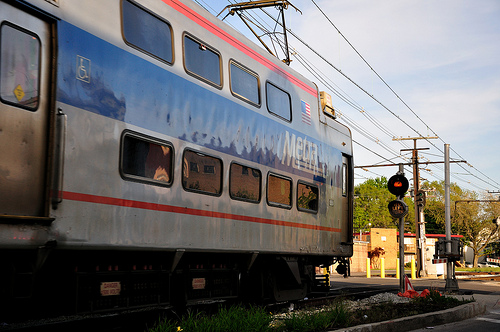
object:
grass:
[187, 302, 348, 331]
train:
[0, 0, 357, 292]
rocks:
[274, 292, 423, 321]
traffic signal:
[387, 167, 420, 295]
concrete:
[393, 253, 499, 318]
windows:
[116, 128, 321, 215]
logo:
[275, 129, 330, 178]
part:
[416, 231, 425, 256]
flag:
[300, 98, 312, 125]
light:
[387, 162, 416, 290]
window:
[116, 129, 177, 188]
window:
[179, 147, 226, 197]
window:
[265, 172, 294, 210]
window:
[295, 177, 320, 215]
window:
[115, 0, 177, 66]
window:
[181, 32, 226, 88]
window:
[227, 56, 262, 108]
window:
[264, 77, 294, 122]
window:
[343, 162, 347, 197]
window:
[0, 19, 42, 111]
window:
[228, 158, 263, 202]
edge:
[452, 304, 477, 319]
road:
[416, 291, 499, 331]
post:
[400, 130, 431, 281]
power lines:
[195, 0, 498, 253]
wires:
[192, 0, 499, 202]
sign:
[73, 55, 93, 85]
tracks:
[260, 284, 397, 315]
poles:
[390, 135, 437, 280]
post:
[365, 257, 372, 278]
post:
[379, 257, 386, 278]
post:
[395, 256, 402, 279]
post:
[411, 257, 418, 279]